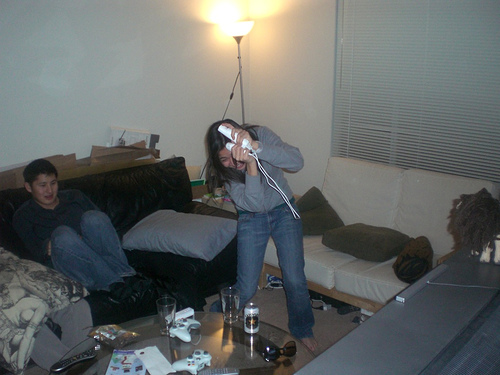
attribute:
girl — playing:
[197, 121, 332, 341]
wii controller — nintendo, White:
[219, 126, 256, 154]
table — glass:
[47, 307, 319, 374]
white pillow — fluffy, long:
[121, 205, 238, 265]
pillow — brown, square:
[319, 220, 411, 263]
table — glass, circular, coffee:
[35, 299, 317, 372]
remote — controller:
[53, 348, 94, 370]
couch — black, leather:
[12, 147, 272, 334]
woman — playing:
[214, 104, 350, 314]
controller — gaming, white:
[168, 347, 218, 374]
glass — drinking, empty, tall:
[218, 295, 245, 325]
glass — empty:
[150, 293, 179, 337]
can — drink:
[243, 302, 259, 334]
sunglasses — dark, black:
[259, 340, 295, 357]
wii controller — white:
[218, 120, 268, 177]